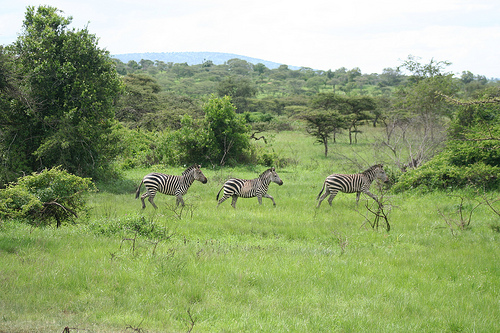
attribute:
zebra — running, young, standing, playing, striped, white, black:
[135, 163, 208, 213]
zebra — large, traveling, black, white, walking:
[215, 167, 283, 208]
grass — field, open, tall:
[2, 129, 500, 333]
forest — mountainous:
[0, 5, 500, 117]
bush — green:
[1, 164, 100, 228]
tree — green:
[303, 110, 351, 157]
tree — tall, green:
[0, 5, 125, 189]